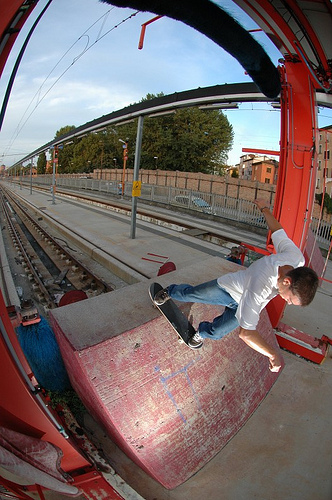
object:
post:
[130, 115, 144, 240]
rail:
[0, 80, 332, 173]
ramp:
[50, 292, 285, 488]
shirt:
[218, 229, 305, 331]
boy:
[149, 197, 318, 374]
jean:
[163, 280, 235, 308]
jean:
[198, 307, 240, 343]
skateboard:
[148, 282, 202, 348]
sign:
[131, 179, 141, 196]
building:
[251, 158, 278, 185]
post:
[267, 62, 316, 253]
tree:
[144, 93, 234, 177]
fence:
[8, 170, 268, 234]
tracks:
[1, 183, 111, 306]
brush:
[14, 317, 71, 398]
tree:
[59, 126, 124, 174]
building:
[239, 155, 253, 180]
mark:
[156, 363, 191, 388]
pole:
[52, 146, 56, 207]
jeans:
[168, 278, 243, 341]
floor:
[84, 288, 332, 497]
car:
[174, 192, 215, 217]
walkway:
[0, 179, 210, 275]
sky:
[0, 0, 332, 170]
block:
[56, 290, 88, 312]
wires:
[0, 0, 131, 134]